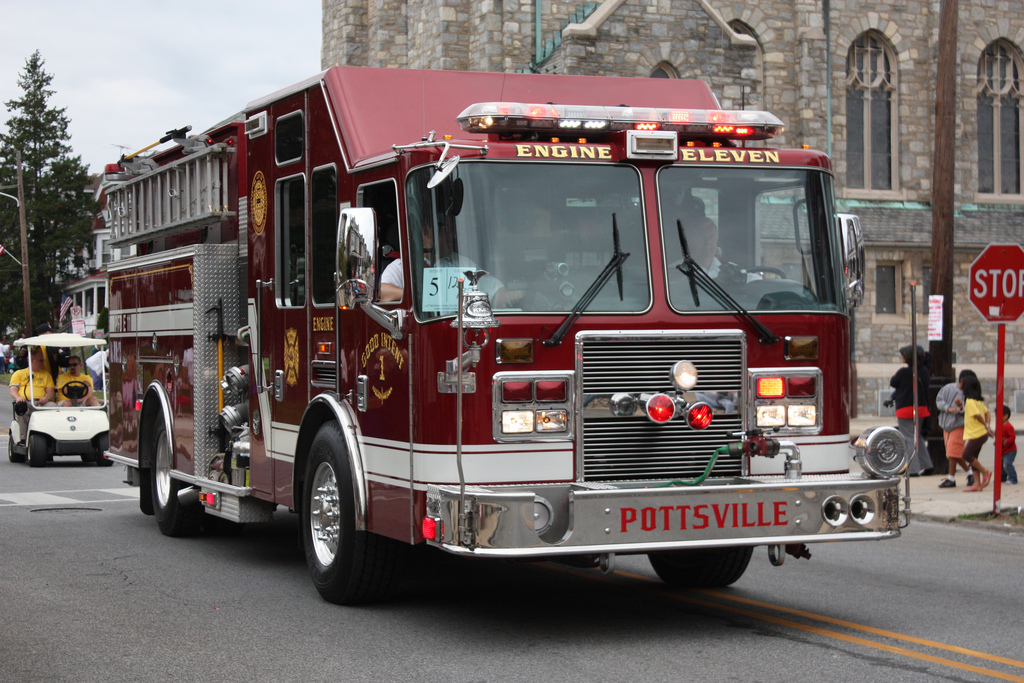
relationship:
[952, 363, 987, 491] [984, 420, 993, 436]
girl holding her little brothers hand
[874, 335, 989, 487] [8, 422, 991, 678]
people waiting to cross street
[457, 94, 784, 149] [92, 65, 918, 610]
light bar on top of fire truck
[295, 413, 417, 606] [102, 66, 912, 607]
tire on a fire engine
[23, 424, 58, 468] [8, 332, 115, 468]
tire in a golf cart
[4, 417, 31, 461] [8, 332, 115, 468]
tire on a golf cart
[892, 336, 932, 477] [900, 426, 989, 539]
person on a sidewalk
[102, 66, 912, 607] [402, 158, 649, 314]
fire engine has window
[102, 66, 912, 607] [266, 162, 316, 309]
fire engine has window